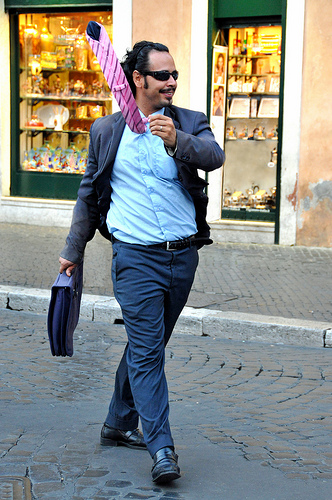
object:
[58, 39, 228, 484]
man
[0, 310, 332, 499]
pavement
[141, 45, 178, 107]
face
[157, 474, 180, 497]
shadow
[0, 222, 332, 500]
ground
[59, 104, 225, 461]
suit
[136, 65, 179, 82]
spects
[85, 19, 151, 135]
tie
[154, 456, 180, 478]
front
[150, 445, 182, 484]
foot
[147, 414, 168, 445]
wrinkles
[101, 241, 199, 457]
pants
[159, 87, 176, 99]
smile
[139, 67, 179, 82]
sunglasses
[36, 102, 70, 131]
various objects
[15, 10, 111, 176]
window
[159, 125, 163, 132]
silver ring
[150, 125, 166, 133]
finger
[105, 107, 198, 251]
shirt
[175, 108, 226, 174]
arm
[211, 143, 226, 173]
elbow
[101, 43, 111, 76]
stripes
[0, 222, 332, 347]
sidewalk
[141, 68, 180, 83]
pair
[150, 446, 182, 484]
shoe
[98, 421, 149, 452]
foot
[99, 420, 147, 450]
shoe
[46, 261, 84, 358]
briefcase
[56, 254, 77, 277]
held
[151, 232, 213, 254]
belt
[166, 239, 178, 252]
buckle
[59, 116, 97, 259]
arm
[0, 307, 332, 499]
street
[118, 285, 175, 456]
leg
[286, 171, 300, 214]
paint peeling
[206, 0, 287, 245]
window trim